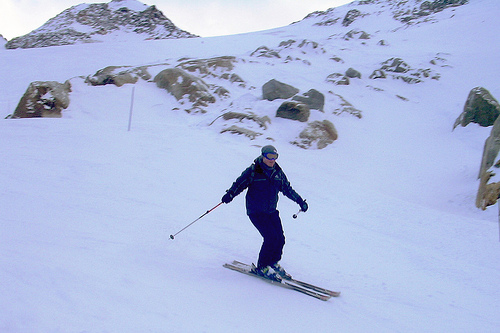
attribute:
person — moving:
[221, 144, 308, 282]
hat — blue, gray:
[261, 144, 277, 155]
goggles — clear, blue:
[262, 150, 279, 159]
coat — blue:
[228, 156, 302, 214]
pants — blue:
[247, 208, 285, 268]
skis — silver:
[223, 260, 341, 300]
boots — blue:
[254, 258, 291, 280]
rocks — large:
[450, 85, 500, 208]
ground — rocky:
[0, 0, 498, 332]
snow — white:
[0, 0, 499, 333]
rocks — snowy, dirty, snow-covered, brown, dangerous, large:
[0, 1, 499, 209]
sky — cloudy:
[0, 1, 353, 40]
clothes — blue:
[222, 159, 302, 267]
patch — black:
[251, 162, 264, 178]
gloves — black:
[221, 190, 309, 212]